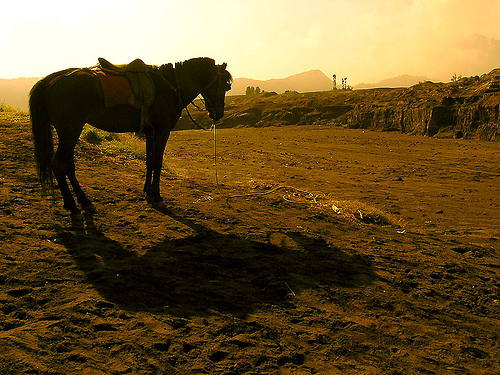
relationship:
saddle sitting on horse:
[90, 59, 156, 137] [27, 55, 232, 212]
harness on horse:
[158, 59, 224, 129] [27, 55, 232, 212]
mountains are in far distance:
[227, 67, 428, 95] [1, 1, 500, 98]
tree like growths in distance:
[242, 82, 262, 98] [1, 1, 500, 98]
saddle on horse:
[90, 59, 156, 137] [27, 55, 232, 212]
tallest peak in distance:
[227, 67, 428, 95] [1, 1, 500, 98]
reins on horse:
[158, 59, 224, 129] [27, 55, 232, 212]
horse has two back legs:
[27, 55, 232, 212] [51, 121, 95, 215]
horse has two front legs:
[27, 55, 232, 212] [142, 121, 172, 209]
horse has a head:
[27, 55, 232, 212] [191, 55, 233, 123]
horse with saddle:
[27, 55, 232, 212] [90, 59, 156, 137]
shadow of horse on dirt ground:
[54, 202, 379, 318] [1, 110, 499, 374]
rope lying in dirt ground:
[209, 125, 402, 233] [1, 110, 499, 374]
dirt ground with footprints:
[1, 110, 499, 374] [5, 285, 157, 334]